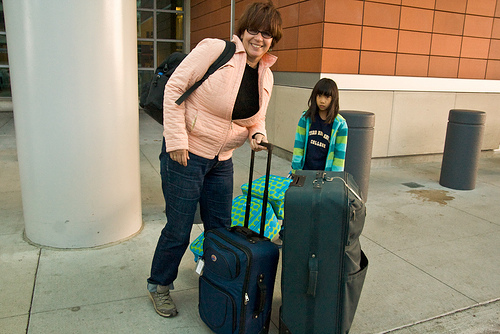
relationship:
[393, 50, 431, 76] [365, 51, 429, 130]
block on wall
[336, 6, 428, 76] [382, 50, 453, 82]
tile on wall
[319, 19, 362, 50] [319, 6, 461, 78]
brick on wall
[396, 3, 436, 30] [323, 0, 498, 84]
tile on wall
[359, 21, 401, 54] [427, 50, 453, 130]
block on wall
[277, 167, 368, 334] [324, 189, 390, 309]
luggage standing upright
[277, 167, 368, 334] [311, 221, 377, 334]
luggage standing upright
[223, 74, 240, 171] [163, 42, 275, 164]
zip up jacket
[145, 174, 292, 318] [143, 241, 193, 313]
jeans with legs rolled up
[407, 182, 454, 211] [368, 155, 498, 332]
stain soiling sidewalk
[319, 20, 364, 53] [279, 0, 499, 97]
block supporting building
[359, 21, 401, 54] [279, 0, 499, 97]
block supporting building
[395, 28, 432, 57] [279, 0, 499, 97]
block supporting building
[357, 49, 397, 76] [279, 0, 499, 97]
block supporting building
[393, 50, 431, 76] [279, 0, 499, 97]
block supporting building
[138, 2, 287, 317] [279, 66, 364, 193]
mom standing next to daughter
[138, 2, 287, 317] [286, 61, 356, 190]
mom standing next to daughter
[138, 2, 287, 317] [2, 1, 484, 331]
mom standing outside airport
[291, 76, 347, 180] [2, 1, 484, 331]
daughter standing outside airport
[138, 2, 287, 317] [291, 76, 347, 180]
mom standing next to daughter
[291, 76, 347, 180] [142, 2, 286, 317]
daughter standing next to mom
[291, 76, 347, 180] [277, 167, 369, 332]
daughter standing next to luggage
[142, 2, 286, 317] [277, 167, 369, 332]
mom standing next to luggage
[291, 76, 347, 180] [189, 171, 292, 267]
daughter holding luggage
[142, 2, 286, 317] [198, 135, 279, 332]
mom holding luggage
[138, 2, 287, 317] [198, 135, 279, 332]
mom holding luggage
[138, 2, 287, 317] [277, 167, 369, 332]
mom standing next to luggage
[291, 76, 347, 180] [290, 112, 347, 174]
daughter wearing jacket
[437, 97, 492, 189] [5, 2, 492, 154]
trashcan standing in front of building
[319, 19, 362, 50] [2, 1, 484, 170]
brick supporting building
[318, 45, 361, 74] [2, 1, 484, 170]
brick supporting building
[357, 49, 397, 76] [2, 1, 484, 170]
block supporting building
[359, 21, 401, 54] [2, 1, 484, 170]
block supporting building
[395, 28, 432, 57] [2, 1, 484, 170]
block supporting building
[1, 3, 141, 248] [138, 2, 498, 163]
white column supporting building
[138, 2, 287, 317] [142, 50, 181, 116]
mom wearing backpack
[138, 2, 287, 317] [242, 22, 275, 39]
mom wearing glasses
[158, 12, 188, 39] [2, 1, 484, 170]
window belonging to building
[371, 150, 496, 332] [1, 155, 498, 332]
part of sidewalk